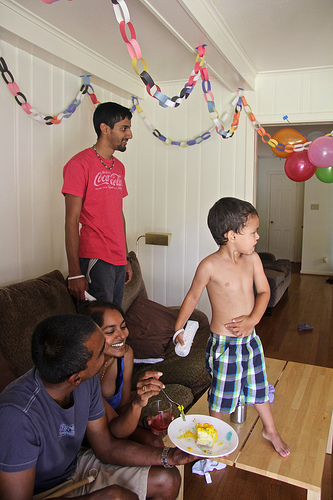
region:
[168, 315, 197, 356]
a large white wii controller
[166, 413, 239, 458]
a white plate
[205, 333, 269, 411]
a boy's plaid shorts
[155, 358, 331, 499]
a brown coffee table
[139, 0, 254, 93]
part of a white column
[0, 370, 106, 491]
a man's short sleeve shirt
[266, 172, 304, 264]
a tall white door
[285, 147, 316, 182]
a red balloon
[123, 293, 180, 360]
a decorative pillow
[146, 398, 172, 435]
a glass with red drink in it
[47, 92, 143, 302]
A man wearing a red shirt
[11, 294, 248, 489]
A man and woman eating cake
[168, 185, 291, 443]
A boy holding a controller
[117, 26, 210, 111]
Paper streamers hung on the ceiling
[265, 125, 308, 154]
An orange balloon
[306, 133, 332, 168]
A pink balloon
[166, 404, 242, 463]
A plate of cake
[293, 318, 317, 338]
A blue shoe on the floor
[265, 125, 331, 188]
A group of balloons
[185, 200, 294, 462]
A boy in plaid shorts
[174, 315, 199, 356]
A white Wii controller.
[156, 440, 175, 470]
A silver wristwatch.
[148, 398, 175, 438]
A clear glass with red liquid inside of it.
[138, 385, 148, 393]
A gold colored ring.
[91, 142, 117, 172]
A necklace.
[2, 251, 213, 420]
A brown couch.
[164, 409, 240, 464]
A white round plate.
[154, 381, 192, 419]
A silver fork.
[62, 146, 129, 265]
A red Coca-Cola shirt.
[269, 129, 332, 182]
Multi-colored balloons.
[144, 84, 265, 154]
colored paper link chain decoration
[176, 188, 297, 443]
boy holding wii controller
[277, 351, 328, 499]
light colored wooden coffee table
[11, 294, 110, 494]
man wearing a grey t-shirt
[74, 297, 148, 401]
woman wearing a blue shirt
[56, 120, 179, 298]
man wearing a red shirt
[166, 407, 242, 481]
white plate with birthday cake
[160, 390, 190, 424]
silver fork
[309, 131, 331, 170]
a pink balloon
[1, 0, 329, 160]
Colorful homemade decorations.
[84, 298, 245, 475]
A woman eating a piece of cake.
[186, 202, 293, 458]
A shirtless young boy.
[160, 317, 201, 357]
A white game controller.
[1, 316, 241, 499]
A man holding a plate.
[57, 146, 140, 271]
A red short-sleeve Coca-Cola shirt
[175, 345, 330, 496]
A wooden folding table.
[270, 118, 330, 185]
Different colored balloons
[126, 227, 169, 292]
A lamp in the corner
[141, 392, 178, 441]
A glass partially filled with liquid